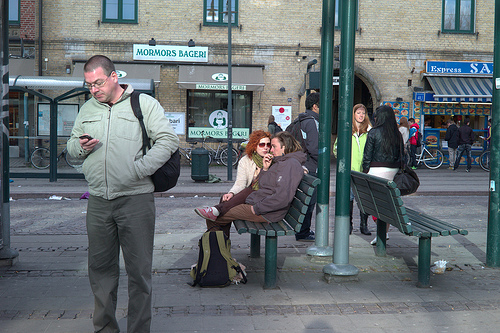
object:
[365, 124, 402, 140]
shoulder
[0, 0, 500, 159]
building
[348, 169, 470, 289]
bench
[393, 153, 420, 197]
backpack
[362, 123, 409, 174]
jacket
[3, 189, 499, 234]
street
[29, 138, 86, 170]
bicycle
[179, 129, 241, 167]
bicycle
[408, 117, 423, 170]
man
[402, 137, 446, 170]
bicycle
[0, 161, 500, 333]
floor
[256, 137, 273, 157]
face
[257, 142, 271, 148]
glasses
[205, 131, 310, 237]
man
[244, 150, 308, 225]
sweatshirt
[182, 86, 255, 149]
window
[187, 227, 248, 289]
backpack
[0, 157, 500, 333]
ground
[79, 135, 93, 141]
cell phone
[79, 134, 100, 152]
hand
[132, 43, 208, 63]
sign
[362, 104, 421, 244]
woman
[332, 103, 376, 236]
woman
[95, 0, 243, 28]
windows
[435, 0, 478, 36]
green frames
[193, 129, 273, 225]
woman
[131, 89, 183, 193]
backpack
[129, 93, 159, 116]
shoulder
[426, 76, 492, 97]
awning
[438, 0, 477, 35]
window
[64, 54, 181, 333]
man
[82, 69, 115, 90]
eye glasses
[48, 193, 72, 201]
garbage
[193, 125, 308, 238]
people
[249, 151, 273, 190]
scarf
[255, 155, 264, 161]
neck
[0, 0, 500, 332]
bus stop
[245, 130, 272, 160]
hair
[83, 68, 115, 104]
man's face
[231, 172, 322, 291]
bench